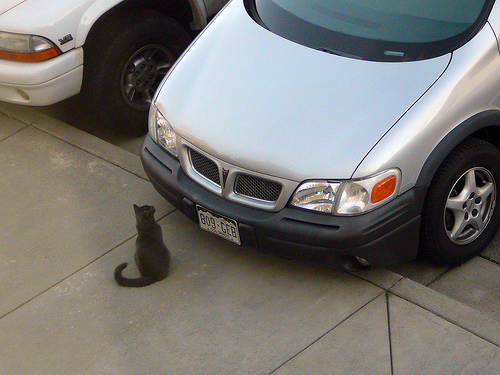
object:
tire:
[417, 136, 500, 263]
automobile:
[138, 0, 498, 279]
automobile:
[0, 0, 229, 138]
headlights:
[152, 109, 180, 160]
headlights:
[28, 35, 57, 53]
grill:
[226, 169, 296, 211]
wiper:
[312, 43, 366, 62]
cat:
[110, 203, 174, 288]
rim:
[444, 165, 499, 245]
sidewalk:
[0, 103, 500, 374]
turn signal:
[368, 175, 398, 205]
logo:
[218, 166, 230, 191]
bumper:
[140, 128, 420, 270]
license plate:
[195, 205, 242, 249]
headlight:
[287, 178, 341, 214]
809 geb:
[192, 204, 246, 249]